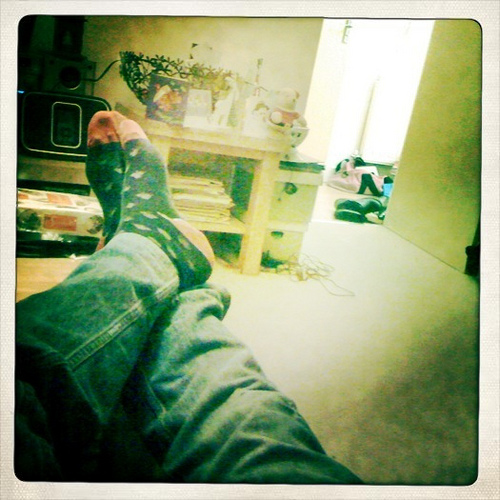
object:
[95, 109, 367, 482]
legs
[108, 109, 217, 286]
feet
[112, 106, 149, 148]
tips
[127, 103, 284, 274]
stand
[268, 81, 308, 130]
teddy bear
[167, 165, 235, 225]
sheets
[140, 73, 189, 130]
book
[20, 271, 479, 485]
floor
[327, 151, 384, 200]
bag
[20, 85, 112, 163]
stereo speaker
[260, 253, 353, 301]
cords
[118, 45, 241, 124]
basket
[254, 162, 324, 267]
boxes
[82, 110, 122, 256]
right sock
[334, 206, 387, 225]
shoes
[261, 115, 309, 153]
bowl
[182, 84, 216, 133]
picture frame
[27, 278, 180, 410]
seam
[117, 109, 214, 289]
sock